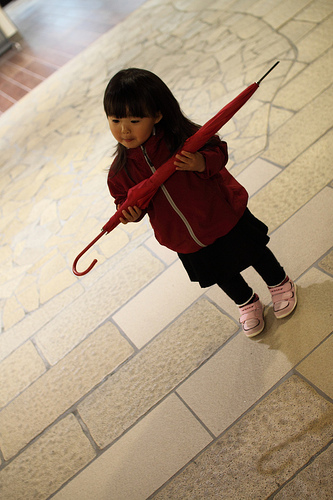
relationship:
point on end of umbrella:
[253, 56, 280, 87] [71, 60, 280, 280]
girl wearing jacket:
[101, 62, 300, 345] [106, 125, 250, 255]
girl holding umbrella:
[101, 62, 300, 345] [71, 60, 280, 280]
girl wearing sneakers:
[101, 62, 300, 345] [236, 281, 298, 339]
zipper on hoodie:
[141, 144, 206, 253] [106, 125, 250, 255]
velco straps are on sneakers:
[267, 284, 293, 304] [236, 281, 298, 339]